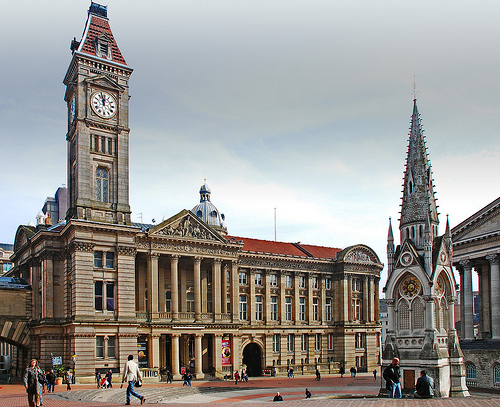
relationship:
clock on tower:
[89, 80, 122, 116] [55, 0, 133, 218]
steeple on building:
[402, 118, 440, 234] [387, 225, 454, 360]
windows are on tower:
[90, 139, 112, 158] [55, 0, 133, 218]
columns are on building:
[148, 252, 159, 319] [387, 225, 454, 360]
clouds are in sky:
[334, 20, 402, 60] [202, 5, 226, 22]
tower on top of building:
[55, 0, 133, 218] [387, 225, 454, 360]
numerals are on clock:
[87, 102, 97, 114] [89, 80, 122, 116]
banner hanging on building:
[218, 337, 235, 367] [387, 225, 454, 360]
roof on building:
[211, 230, 314, 256] [387, 225, 454, 360]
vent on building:
[86, 21, 111, 37] [387, 225, 454, 360]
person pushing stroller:
[382, 363, 404, 394] [94, 375, 109, 388]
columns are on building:
[140, 271, 184, 312] [387, 225, 454, 360]